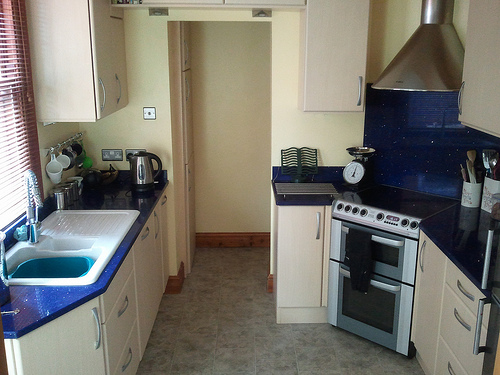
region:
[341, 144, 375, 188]
A food scale with a large round dial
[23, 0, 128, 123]
Kitchen cupboards with doors mounted to a wall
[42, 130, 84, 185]
Coffee mugs hanging from a metal rod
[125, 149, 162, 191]
A silver coffee pot with black handles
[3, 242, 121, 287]
A turquoise plastic bin sitting in a sink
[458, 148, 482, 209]
A container holding several kitchen utensils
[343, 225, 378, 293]
A dark dish towel hanging from the oven door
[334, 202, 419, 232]
Round dials for the oven and stove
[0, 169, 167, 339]
A vibrant blue kitchen countertop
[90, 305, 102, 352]
A metal handle for a kitchen cabinet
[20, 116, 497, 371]
a kitchen in a house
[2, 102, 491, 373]
a kitchen in an apartment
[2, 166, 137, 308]
a sink in a kitchen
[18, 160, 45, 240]
a faucet in a kitchen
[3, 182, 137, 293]
a white sink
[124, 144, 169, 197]
an electric coffee pot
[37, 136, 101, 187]
cups hanging on the wall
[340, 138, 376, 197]
a scale on the counter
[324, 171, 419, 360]
a stove top and oven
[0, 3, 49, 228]
a window in the kitchen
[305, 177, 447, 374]
stainless steel stove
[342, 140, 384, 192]
silver scale on table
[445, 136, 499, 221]
utensils in containers on counter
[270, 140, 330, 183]
recipe book holder on counter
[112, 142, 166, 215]
stainless steel and black kettle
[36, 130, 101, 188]
cups hanging on rack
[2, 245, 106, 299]
blue bucket in sink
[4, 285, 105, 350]
blue counter top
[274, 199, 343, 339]
cream kitchen cabinet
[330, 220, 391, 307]
black towel on stove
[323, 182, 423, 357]
a stove in the corner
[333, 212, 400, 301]
a towel hangs from stove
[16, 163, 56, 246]
a faucett over a sink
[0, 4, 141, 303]
a window in front a sink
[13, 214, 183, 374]
cabinets under a sink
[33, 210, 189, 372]
cabinets under a sink are white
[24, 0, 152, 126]
cabinets over a counter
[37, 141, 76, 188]
white cups hang from wall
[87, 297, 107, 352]
a handle on a cabinet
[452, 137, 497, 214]
white holder with utensils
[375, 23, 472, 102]
A stainless steal overhead exhaust.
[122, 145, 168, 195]
A coffee carafe.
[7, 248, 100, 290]
A blue tub in a white sink.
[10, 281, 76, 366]
Blue counters over white cabinets.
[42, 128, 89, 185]
A row of hanging measuring cups.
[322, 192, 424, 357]
A stainless steel double oven.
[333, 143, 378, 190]
A stainless steel scale.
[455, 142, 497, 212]
The utensils are in canisters.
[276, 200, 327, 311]
Silver metal handle on a cabinet.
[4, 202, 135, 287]
The sink is white.